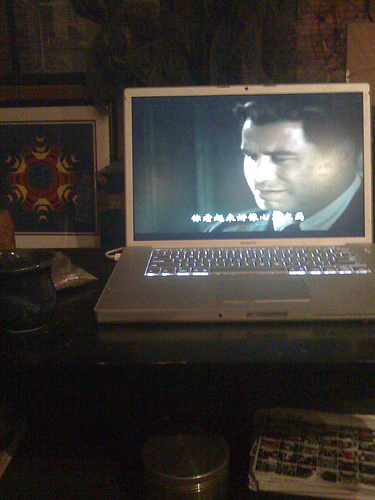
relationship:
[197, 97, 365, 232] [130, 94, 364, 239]
man on a screen